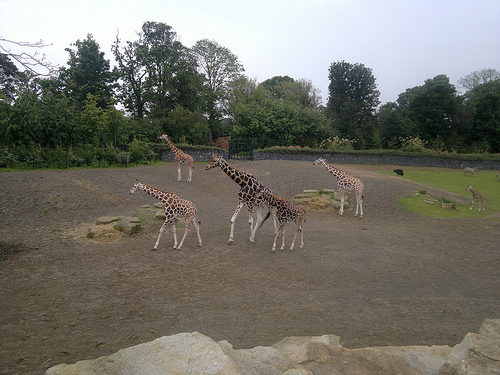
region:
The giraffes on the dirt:
[121, 125, 364, 260]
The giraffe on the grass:
[460, 180, 490, 216]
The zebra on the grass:
[459, 160, 483, 180]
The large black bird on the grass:
[390, 164, 412, 181]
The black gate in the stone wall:
[224, 136, 256, 163]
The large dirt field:
[1, 156, 499, 373]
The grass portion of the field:
[378, 160, 498, 226]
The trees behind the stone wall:
[0, 13, 498, 170]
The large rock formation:
[41, 311, 498, 373]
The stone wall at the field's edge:
[156, 139, 498, 169]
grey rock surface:
[103, 327, 290, 372]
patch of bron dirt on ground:
[249, 271, 334, 314]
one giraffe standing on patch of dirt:
[301, 151, 385, 225]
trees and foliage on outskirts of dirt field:
[3, 17, 116, 168]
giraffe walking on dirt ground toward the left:
[125, 176, 216, 261]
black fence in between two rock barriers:
[224, 133, 262, 164]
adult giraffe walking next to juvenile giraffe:
[201, 148, 316, 258]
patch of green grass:
[432, 171, 462, 191]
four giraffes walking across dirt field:
[125, 126, 321, 276]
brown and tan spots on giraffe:
[238, 173, 254, 193]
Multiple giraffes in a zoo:
[120, 128, 491, 276]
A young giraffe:
[250, 194, 312, 246]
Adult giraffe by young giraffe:
[199, 149, 281, 244]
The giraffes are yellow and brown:
[132, 129, 382, 256]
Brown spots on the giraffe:
[165, 200, 189, 212]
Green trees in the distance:
[35, 40, 466, 145]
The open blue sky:
[370, 8, 439, 60]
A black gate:
[230, 140, 256, 162]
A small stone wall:
[254, 144, 492, 174]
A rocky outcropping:
[93, 208, 160, 233]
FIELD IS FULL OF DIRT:
[10, 275, 75, 296]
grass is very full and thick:
[435, 170, 450, 181]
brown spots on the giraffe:
[165, 195, 170, 200]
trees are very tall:
[265, 100, 290, 120]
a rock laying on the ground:
[110, 220, 120, 230]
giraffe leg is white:
[230, 210, 235, 240]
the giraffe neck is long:
[315, 150, 340, 185]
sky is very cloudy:
[315, 20, 370, 45]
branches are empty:
[15, 40, 45, 65]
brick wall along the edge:
[265, 151, 301, 161]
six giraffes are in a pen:
[122, 130, 499, 261]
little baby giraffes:
[256, 150, 488, 251]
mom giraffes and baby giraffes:
[11, 105, 485, 265]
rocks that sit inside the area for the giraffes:
[68, 204, 155, 256]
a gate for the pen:
[214, 130, 267, 167]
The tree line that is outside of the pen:
[1, 18, 497, 170]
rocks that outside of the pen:
[27, 307, 497, 373]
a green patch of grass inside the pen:
[363, 157, 499, 232]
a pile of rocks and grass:
[293, 176, 343, 218]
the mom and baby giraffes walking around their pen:
[20, 7, 499, 360]